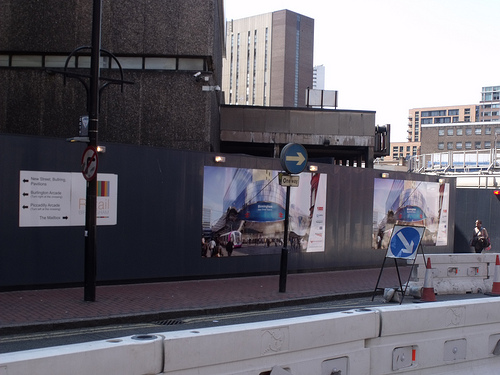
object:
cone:
[483, 250, 500, 300]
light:
[215, 155, 227, 163]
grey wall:
[0, 132, 477, 289]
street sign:
[387, 224, 432, 261]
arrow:
[397, 229, 414, 254]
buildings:
[476, 84, 499, 122]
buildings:
[402, 100, 478, 143]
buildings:
[416, 120, 499, 155]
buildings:
[383, 141, 421, 162]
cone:
[420, 256, 437, 302]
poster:
[372, 175, 451, 253]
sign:
[284, 142, 310, 175]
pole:
[278, 184, 291, 293]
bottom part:
[278, 244, 288, 292]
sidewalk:
[1, 254, 497, 334]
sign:
[80, 142, 102, 179]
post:
[84, 2, 105, 303]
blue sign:
[283, 141, 308, 173]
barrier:
[1, 134, 454, 291]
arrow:
[286, 152, 306, 166]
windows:
[421, 110, 446, 117]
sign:
[281, 138, 308, 173]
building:
[220, 8, 315, 107]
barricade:
[0, 292, 500, 375]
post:
[278, 186, 291, 294]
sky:
[325, 0, 483, 100]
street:
[5, 287, 380, 356]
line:
[4, 294, 378, 344]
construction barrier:
[22, 290, 498, 371]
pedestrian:
[471, 219, 491, 253]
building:
[312, 62, 327, 91]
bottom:
[84, 0, 105, 303]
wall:
[116, 152, 186, 282]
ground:
[221, 269, 471, 308]